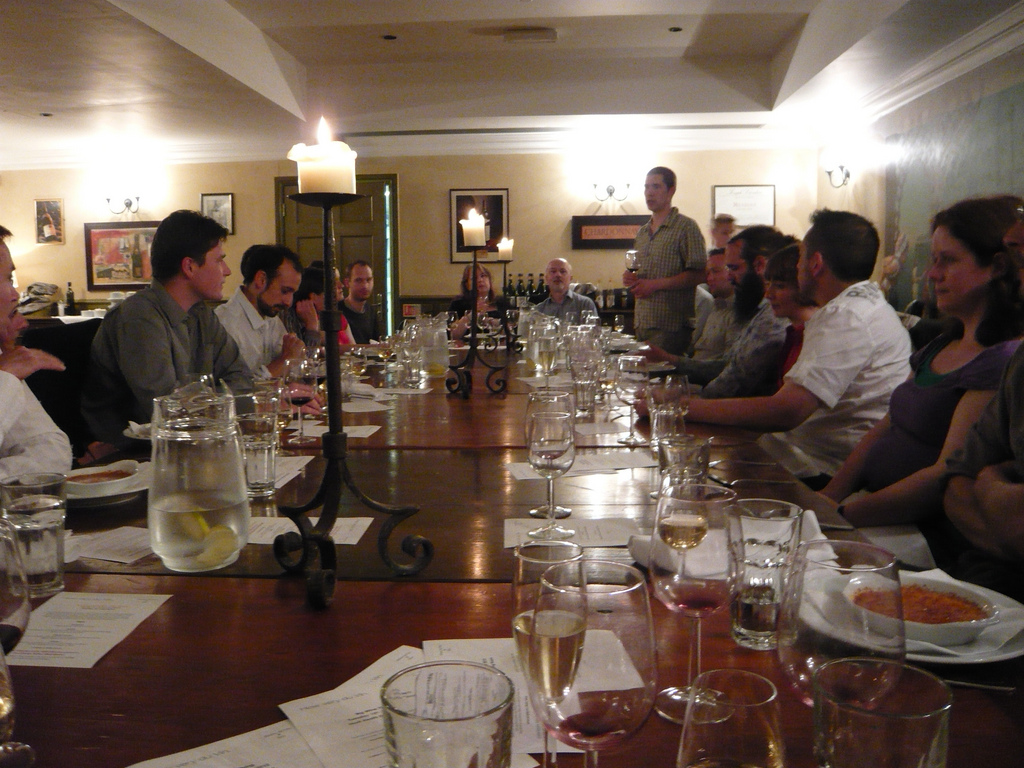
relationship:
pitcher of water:
[143, 374, 247, 567] [156, 428, 245, 567]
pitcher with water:
[147, 379, 249, 573] [152, 419, 246, 566]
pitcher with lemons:
[147, 379, 249, 573] [167, 504, 239, 563]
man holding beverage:
[622, 165, 709, 356] [621, 248, 639, 294]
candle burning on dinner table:
[287, 113, 358, 195] [0, 340, 1024, 768]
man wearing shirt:
[638, 210, 911, 483] [761, 279, 911, 489]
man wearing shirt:
[87, 207, 258, 428] [91, 285, 260, 417]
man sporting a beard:
[632, 224, 786, 398] [729, 270, 766, 322]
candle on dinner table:
[286, 108, 360, 195] [0, 340, 1024, 768]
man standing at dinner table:
[621, 164, 706, 348] [3, 318, 1017, 757]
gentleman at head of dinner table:
[528, 251, 598, 323] [0, 340, 1024, 768]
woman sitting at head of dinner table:
[447, 263, 510, 340] [0, 340, 1024, 768]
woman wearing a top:
[811, 192, 1021, 555] [873, 324, 1005, 508]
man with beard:
[696, 223, 800, 390] [725, 266, 762, 321]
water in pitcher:
[157, 445, 237, 564] [142, 369, 256, 581]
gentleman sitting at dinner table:
[536, 258, 599, 328] [0, 340, 1024, 768]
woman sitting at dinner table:
[438, 253, 512, 330] [0, 340, 1024, 768]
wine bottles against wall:
[504, 269, 562, 295] [391, 214, 639, 318]